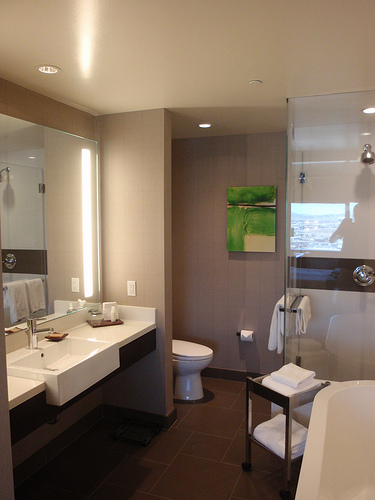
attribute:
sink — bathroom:
[16, 333, 120, 392]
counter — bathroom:
[12, 302, 170, 396]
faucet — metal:
[25, 317, 54, 350]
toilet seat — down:
[170, 335, 213, 360]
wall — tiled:
[171, 132, 374, 381]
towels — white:
[5, 276, 45, 321]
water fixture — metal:
[22, 317, 54, 348]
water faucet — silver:
[23, 317, 52, 351]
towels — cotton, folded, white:
[260, 361, 322, 397]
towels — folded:
[250, 362, 322, 460]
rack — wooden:
[241, 362, 329, 484]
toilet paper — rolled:
[240, 328, 254, 341]